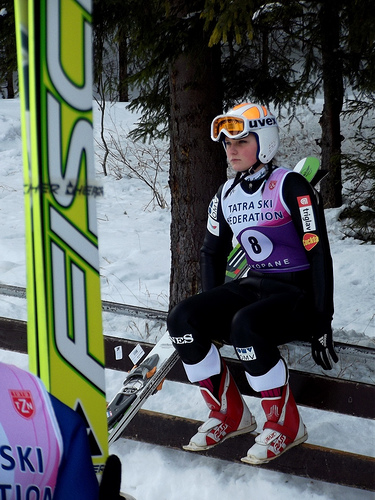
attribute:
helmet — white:
[210, 102, 283, 166]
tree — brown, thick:
[95, 1, 292, 335]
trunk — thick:
[160, 10, 235, 321]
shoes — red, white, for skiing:
[242, 360, 310, 467]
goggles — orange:
[209, 112, 278, 144]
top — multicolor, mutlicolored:
[202, 165, 338, 325]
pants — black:
[167, 270, 327, 374]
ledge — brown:
[2, 284, 375, 492]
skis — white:
[107, 155, 328, 447]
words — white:
[47, 2, 107, 402]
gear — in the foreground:
[14, 0, 112, 492]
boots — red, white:
[180, 344, 309, 467]